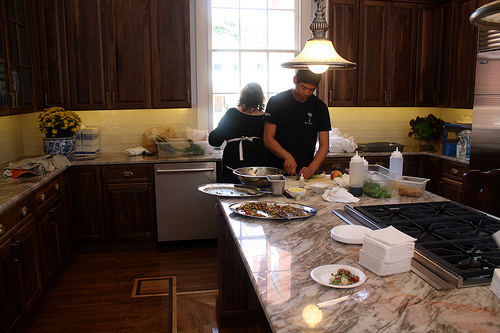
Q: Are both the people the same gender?
A: No, they are both male and female.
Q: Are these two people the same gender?
A: No, they are both male and female.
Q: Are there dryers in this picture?
A: No, there are no dryers.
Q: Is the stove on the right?
A: Yes, the stove is on the right of the image.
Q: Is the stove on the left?
A: No, the stove is on the right of the image.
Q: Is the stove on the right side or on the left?
A: The stove is on the right of the image.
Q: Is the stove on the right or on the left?
A: The stove is on the right of the image.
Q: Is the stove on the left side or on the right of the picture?
A: The stove is on the right of the image.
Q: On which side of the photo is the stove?
A: The stove is on the right of the image.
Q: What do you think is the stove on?
A: The stove is on the counter.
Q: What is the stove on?
A: The stove is on the counter.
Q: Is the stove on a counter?
A: Yes, the stove is on a counter.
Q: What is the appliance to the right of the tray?
A: The appliance is a stove.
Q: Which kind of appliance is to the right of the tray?
A: The appliance is a stove.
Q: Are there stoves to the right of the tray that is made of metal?
A: Yes, there is a stove to the right of the tray.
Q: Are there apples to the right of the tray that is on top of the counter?
A: No, there is a stove to the right of the tray.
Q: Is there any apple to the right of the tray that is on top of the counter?
A: No, there is a stove to the right of the tray.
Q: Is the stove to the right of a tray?
A: Yes, the stove is to the right of a tray.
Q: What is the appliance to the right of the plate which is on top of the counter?
A: The appliance is a stove.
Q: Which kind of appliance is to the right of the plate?
A: The appliance is a stove.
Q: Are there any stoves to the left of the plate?
A: No, the stove is to the right of the plate.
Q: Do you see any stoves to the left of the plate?
A: No, the stove is to the right of the plate.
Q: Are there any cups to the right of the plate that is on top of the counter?
A: No, there is a stove to the right of the plate.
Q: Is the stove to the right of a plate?
A: Yes, the stove is to the right of a plate.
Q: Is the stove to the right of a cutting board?
A: No, the stove is to the right of a plate.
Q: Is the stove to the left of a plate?
A: No, the stove is to the right of a plate.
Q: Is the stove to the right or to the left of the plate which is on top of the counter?
A: The stove is to the right of the plate.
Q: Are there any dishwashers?
A: Yes, there is a dishwasher.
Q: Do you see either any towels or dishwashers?
A: Yes, there is a dishwasher.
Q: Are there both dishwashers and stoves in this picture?
A: Yes, there are both a dishwasher and a stove.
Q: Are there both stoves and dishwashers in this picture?
A: Yes, there are both a dishwasher and a stove.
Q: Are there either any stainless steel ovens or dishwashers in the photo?
A: Yes, there is a stainless steel dishwasher.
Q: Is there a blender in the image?
A: No, there are no blenders.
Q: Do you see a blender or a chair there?
A: No, there are no blenders or chairs.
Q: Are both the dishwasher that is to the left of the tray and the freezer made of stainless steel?
A: Yes, both the dish washer and the freezer are made of stainless steel.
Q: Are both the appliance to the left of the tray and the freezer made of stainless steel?
A: Yes, both the dish washer and the freezer are made of stainless steel.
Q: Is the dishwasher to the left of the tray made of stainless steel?
A: Yes, the dish washer is made of stainless steel.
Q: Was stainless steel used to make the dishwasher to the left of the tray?
A: Yes, the dish washer is made of stainless steel.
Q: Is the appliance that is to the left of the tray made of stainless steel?
A: Yes, the dish washer is made of stainless steel.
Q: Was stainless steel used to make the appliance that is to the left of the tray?
A: Yes, the dish washer is made of stainless steel.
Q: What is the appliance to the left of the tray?
A: The appliance is a dishwasher.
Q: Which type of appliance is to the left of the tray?
A: The appliance is a dishwasher.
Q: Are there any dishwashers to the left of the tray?
A: Yes, there is a dishwasher to the left of the tray.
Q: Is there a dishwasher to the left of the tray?
A: Yes, there is a dishwasher to the left of the tray.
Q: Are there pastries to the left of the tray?
A: No, there is a dishwasher to the left of the tray.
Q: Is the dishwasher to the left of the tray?
A: Yes, the dishwasher is to the left of the tray.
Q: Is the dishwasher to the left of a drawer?
A: No, the dishwasher is to the left of the tray.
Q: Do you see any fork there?
A: Yes, there is a fork.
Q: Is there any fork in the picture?
A: Yes, there is a fork.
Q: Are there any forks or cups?
A: Yes, there is a fork.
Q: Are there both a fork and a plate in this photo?
A: Yes, there are both a fork and a plate.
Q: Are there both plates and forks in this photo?
A: Yes, there are both a fork and a plate.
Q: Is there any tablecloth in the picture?
A: No, there are no tablecloths.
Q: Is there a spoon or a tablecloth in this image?
A: No, there are no tablecloths or spoons.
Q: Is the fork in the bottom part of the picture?
A: Yes, the fork is in the bottom of the image.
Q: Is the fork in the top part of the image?
A: No, the fork is in the bottom of the image.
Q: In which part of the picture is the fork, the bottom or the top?
A: The fork is in the bottom of the image.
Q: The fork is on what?
A: The fork is on the counter.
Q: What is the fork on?
A: The fork is on the counter.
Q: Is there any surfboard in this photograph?
A: No, there are no surfboards.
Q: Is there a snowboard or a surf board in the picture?
A: No, there are no surfboards or snowboards.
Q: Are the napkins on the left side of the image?
A: No, the napkins are on the right of the image.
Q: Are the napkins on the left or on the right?
A: The napkins are on the right of the image.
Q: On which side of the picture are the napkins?
A: The napkins are on the right of the image.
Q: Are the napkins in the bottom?
A: Yes, the napkins are in the bottom of the image.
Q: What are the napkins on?
A: The napkins are on the counter.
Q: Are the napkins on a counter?
A: Yes, the napkins are on a counter.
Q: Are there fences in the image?
A: No, there are no fences.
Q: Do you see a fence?
A: No, there are no fences.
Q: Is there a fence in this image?
A: No, there are no fences.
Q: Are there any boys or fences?
A: No, there are no fences or boys.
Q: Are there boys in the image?
A: No, there are no boys.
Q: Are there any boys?
A: No, there are no boys.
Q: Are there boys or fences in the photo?
A: No, there are no boys or fences.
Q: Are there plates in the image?
A: Yes, there is a plate.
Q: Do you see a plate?
A: Yes, there is a plate.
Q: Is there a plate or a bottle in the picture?
A: Yes, there is a plate.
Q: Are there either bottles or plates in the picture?
A: Yes, there is a plate.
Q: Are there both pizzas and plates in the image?
A: No, there is a plate but no pizzas.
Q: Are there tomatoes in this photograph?
A: No, there are no tomatoes.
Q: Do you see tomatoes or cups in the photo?
A: No, there are no tomatoes or cups.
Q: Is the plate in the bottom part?
A: Yes, the plate is in the bottom of the image.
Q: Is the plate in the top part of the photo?
A: No, the plate is in the bottom of the image.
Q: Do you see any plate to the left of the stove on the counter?
A: Yes, there is a plate to the left of the stove.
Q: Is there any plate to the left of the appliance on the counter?
A: Yes, there is a plate to the left of the stove.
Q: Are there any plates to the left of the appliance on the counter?
A: Yes, there is a plate to the left of the stove.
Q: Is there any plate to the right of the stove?
A: No, the plate is to the left of the stove.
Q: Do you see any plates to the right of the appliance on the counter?
A: No, the plate is to the left of the stove.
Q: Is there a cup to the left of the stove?
A: No, there is a plate to the left of the stove.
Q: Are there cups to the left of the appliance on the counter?
A: No, there is a plate to the left of the stove.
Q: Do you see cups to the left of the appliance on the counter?
A: No, there is a plate to the left of the stove.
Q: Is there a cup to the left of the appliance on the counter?
A: No, there is a plate to the left of the stove.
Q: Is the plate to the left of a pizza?
A: No, the plate is to the left of a stove.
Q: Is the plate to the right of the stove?
A: No, the plate is to the left of the stove.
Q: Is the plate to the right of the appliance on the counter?
A: No, the plate is to the left of the stove.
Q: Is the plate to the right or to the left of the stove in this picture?
A: The plate is to the left of the stove.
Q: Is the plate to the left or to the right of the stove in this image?
A: The plate is to the left of the stove.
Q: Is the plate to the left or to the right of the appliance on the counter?
A: The plate is to the left of the stove.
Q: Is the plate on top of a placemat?
A: No, the plate is on top of a counter.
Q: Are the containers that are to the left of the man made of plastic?
A: Yes, the containers are made of plastic.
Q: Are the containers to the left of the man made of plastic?
A: Yes, the containers are made of plastic.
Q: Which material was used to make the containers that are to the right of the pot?
A: The containers are made of plastic.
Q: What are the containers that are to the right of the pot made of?
A: The containers are made of plastic.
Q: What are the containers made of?
A: The containers are made of plastic.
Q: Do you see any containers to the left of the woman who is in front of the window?
A: Yes, there are containers to the left of the woman.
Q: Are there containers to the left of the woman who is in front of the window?
A: Yes, there are containers to the left of the woman.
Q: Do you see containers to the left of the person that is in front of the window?
A: Yes, there are containers to the left of the woman.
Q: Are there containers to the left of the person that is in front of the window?
A: Yes, there are containers to the left of the woman.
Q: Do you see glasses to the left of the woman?
A: No, there are containers to the left of the woman.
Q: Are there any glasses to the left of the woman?
A: No, there are containers to the left of the woman.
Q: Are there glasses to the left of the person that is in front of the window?
A: No, there are containers to the left of the woman.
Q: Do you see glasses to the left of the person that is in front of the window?
A: No, there are containers to the left of the woman.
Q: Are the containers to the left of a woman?
A: Yes, the containers are to the left of a woman.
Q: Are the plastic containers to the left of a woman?
A: Yes, the containers are to the left of a woman.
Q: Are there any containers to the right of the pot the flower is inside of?
A: Yes, there are containers to the right of the pot.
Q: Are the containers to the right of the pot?
A: Yes, the containers are to the right of the pot.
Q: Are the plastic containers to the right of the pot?
A: Yes, the containers are to the right of the pot.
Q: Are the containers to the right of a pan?
A: No, the containers are to the right of the pot.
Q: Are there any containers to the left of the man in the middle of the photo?
A: Yes, there are containers to the left of the man.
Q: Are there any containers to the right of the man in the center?
A: No, the containers are to the left of the man.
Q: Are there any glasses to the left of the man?
A: No, there are containers to the left of the man.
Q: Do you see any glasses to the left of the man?
A: No, there are containers to the left of the man.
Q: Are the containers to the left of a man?
A: Yes, the containers are to the left of a man.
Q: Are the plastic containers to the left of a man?
A: Yes, the containers are to the left of a man.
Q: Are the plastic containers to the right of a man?
A: No, the containers are to the left of a man.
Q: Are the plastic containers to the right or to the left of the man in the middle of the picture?
A: The containers are to the left of the man.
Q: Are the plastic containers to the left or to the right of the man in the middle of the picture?
A: The containers are to the left of the man.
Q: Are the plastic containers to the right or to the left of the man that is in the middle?
A: The containers are to the left of the man.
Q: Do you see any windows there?
A: Yes, there is a window.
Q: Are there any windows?
A: Yes, there is a window.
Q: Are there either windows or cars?
A: Yes, there is a window.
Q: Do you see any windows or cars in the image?
A: Yes, there is a window.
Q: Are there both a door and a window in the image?
A: No, there is a window but no doors.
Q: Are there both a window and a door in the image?
A: No, there is a window but no doors.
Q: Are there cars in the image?
A: No, there are no cars.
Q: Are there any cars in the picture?
A: No, there are no cars.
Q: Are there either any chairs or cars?
A: No, there are no cars or chairs.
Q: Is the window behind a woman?
A: Yes, the window is behind a woman.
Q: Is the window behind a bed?
A: No, the window is behind a woman.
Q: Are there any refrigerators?
A: Yes, there is a refrigerator.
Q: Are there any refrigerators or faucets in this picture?
A: Yes, there is a refrigerator.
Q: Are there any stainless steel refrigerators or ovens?
A: Yes, there is a stainless steel refrigerator.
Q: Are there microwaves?
A: No, there are no microwaves.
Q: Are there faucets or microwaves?
A: No, there are no microwaves or faucets.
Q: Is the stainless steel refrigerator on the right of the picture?
A: Yes, the freezer is on the right of the image.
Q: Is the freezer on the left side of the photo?
A: No, the freezer is on the right of the image.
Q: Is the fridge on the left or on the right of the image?
A: The fridge is on the right of the image.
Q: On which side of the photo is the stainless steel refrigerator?
A: The refrigerator is on the right of the image.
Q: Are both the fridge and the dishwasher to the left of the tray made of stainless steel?
A: Yes, both the fridge and the dishwasher are made of stainless steel.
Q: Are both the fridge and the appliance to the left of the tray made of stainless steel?
A: Yes, both the fridge and the dishwasher are made of stainless steel.